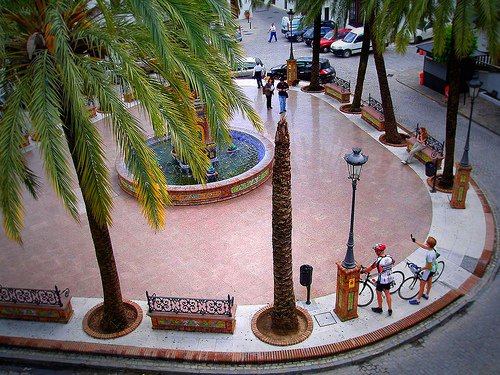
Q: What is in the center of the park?
A: A fountain.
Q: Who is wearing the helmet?
A: A man.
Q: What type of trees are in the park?
A: Palm trees.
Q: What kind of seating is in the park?
A: Benches.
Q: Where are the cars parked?
A: On street.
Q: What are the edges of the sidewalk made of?
A: Brick.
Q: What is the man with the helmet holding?
A: A bicycle.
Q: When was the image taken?
A: In the afternoon.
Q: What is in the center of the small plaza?
A: A fountain.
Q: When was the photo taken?
A: During daylight hours.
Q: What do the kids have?
A: Bikes.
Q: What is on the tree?
A: Many leaves.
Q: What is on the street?
A: Cars.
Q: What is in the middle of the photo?
A: Water.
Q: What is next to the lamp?
A: The street.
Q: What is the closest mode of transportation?
A: Bicycle.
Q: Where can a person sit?
A: Bench.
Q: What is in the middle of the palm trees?
A: Fountain.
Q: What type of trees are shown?
A: Palm tree.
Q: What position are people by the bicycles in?
A: Standing.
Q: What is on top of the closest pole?
A: Light.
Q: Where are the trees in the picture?
A: On the sidewalk.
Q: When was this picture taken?
A: Daytime.